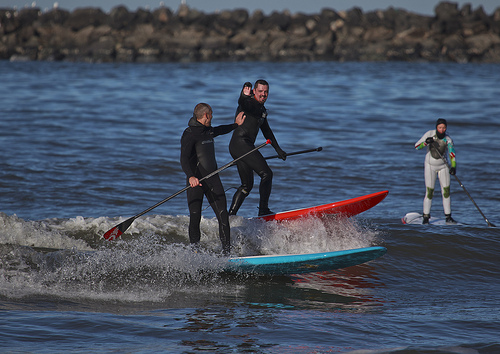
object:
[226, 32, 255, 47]
rocks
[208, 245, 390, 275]
board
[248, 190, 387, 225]
paddle board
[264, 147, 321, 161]
paddle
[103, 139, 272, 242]
paddle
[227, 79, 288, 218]
boarder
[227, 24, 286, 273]
middle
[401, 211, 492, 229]
paddle board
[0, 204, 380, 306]
wave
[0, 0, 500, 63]
rock jetty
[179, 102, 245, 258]
boarders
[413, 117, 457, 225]
boarders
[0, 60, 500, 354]
water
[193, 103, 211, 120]
hair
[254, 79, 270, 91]
hair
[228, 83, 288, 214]
wet suit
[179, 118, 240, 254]
wet suit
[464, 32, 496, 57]
rocks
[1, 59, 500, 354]
ocean